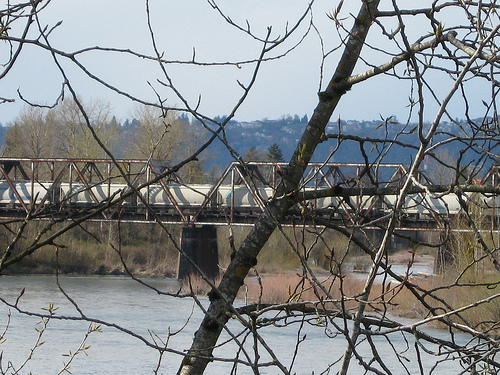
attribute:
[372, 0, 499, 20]
branch — leafless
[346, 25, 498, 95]
branch — leafless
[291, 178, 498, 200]
branch — leafless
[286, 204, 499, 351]
branch — leafless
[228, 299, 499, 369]
branch — leafless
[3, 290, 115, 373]
branches — green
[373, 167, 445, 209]
branch — skinny , small 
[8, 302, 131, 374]
vegetation —  light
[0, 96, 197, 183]
tree — here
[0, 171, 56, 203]
car — white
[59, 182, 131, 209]
car — white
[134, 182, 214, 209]
car — white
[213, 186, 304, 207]
car — white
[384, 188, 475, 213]
car — white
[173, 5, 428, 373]
trunk — dark, brown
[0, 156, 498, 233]
bridge — metal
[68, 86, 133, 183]
branch — small, skinny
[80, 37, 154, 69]
branch — small, skinny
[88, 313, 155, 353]
branch — small, skinny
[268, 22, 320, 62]
branch — small, skinny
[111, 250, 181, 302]
branch — small, skinny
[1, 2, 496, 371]
tree — small, skinny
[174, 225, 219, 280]
base — cement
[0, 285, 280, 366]
branch — small , skinny 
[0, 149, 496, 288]
bridge — metal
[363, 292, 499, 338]
tree branch — small, skinny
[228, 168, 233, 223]
girding — silver, some, here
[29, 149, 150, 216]
railing — metal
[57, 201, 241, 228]
bridge — stone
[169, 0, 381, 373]
tree branch — skinny, small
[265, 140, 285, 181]
tree — evergreen tree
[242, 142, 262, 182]
tree — evergreen tree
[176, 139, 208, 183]
tree — evergreen tree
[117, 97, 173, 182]
tree — evergreen tree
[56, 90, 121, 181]
tree — evergreen tree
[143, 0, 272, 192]
branch — small, skinny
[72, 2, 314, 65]
branch — skinny, small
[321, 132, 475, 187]
branch — skinny, small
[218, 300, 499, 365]
branch — skinny, small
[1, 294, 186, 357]
branch — skinny, small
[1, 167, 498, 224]
train —  white 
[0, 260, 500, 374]
river —  light brown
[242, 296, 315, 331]
sticks — empty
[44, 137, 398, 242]
photo — taken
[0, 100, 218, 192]
trees — light green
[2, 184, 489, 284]
bridge — metal